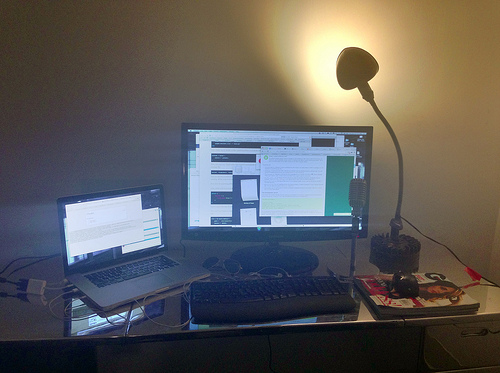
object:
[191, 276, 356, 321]
computer keyboard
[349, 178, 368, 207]
microphone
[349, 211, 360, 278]
stand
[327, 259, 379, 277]
base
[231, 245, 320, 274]
base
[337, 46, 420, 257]
lamp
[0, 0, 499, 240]
wall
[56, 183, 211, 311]
computer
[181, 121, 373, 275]
computer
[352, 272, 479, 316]
magazines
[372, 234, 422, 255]
base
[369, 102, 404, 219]
arm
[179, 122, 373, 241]
computer monitor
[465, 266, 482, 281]
red tag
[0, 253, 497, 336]
glass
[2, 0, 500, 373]
interior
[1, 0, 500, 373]
room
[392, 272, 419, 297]
computer mouse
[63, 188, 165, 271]
panel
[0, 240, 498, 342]
desk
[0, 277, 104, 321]
cords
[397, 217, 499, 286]
black cord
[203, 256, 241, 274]
sunglasses